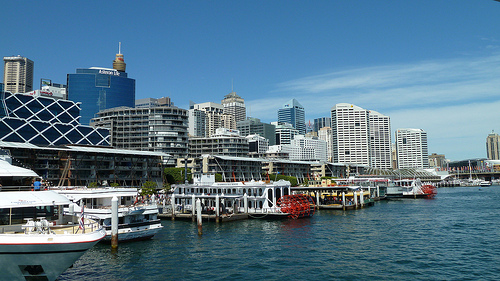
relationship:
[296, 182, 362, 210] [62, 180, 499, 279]
pier that extends into harbor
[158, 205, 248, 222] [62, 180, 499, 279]
pier that extends into harbor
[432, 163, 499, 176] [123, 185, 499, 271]
flag installed near river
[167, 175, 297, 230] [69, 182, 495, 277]
yacht floating on a river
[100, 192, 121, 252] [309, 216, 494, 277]
post sticking out of river